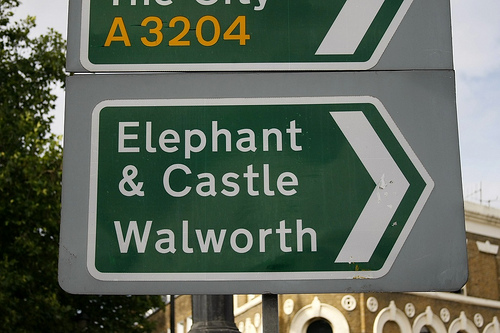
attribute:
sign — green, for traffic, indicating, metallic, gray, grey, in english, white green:
[57, 71, 470, 298]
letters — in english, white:
[117, 120, 303, 156]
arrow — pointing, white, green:
[328, 108, 411, 269]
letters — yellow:
[102, 12, 251, 51]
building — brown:
[139, 199, 500, 332]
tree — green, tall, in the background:
[3, 2, 166, 332]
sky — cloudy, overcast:
[3, 1, 499, 207]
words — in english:
[112, 163, 323, 257]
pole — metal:
[182, 293, 239, 332]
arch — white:
[285, 297, 349, 332]